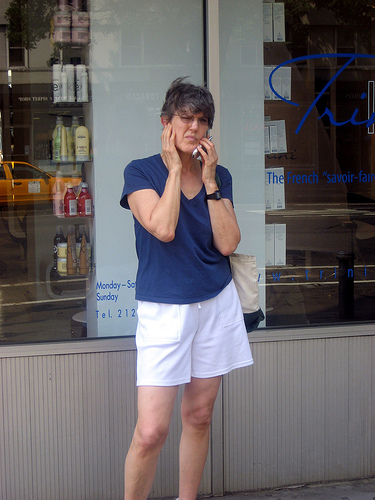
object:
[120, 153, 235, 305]
blue shirt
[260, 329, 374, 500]
wall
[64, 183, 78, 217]
bottle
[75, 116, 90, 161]
bottle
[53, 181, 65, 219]
bottle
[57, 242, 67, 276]
bottle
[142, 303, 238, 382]
white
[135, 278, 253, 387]
shorts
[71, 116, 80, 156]
bottle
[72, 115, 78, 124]
cap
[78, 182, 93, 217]
bottle